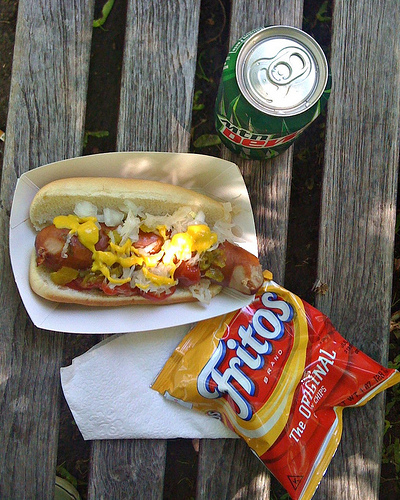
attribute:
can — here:
[212, 25, 329, 162]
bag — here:
[151, 268, 399, 499]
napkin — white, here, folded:
[59, 321, 242, 440]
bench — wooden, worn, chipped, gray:
[0, 2, 399, 500]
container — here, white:
[9, 151, 260, 334]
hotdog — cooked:
[34, 224, 265, 295]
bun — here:
[29, 176, 233, 308]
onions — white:
[74, 200, 125, 228]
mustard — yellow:
[52, 214, 216, 286]